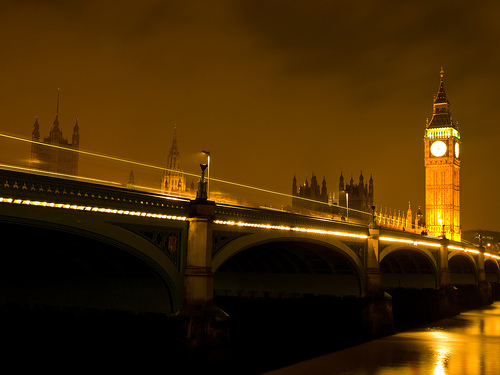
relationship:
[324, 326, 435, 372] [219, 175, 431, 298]
water under bridge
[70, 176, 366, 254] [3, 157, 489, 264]
lights on top of freeway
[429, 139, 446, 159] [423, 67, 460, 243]
clock on big ben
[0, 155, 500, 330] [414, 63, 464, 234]
bridge next to clock tower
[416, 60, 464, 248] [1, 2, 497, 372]
big ben in london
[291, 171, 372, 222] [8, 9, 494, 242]
building in background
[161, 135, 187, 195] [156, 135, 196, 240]
top of structure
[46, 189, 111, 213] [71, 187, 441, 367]
lights on side of bridge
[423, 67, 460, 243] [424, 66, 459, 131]
big ben has top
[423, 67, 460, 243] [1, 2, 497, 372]
big ben on london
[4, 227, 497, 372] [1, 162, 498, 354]
shadow beneath bridge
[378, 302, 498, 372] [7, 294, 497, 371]
reflection in river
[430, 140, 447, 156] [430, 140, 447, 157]
clock has clock face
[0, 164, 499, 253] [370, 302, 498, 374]
freeway going on river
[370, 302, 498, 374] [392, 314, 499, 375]
river has reflection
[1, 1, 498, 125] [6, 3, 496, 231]
sky has cloud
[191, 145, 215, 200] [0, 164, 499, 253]
street lamp light freeway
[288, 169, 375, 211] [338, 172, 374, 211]
building has top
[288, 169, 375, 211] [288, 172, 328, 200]
building has top